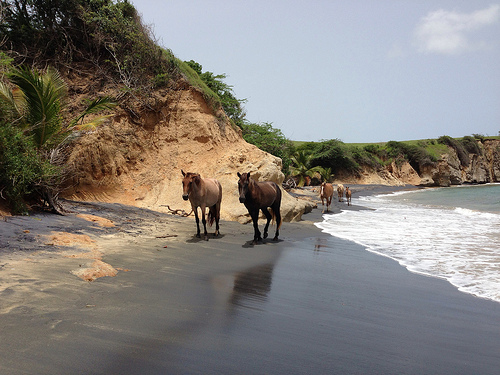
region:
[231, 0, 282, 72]
part of the sky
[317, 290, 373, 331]
edge of a shore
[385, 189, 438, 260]
part of a water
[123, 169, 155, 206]
part of a roack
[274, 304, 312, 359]
part of a shore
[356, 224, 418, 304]
edge of a shore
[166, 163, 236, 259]
Large brown animal walking on the beach.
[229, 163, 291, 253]
Dark brown animal walking on the beach.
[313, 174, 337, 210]
Brown animal walking on the beach.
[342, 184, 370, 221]
Brown animal walking along the beach.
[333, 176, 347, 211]
Brown animal walking along the beach.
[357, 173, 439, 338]
Waves washing up on shore.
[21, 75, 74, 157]
Large green leaves on plant.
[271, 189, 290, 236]
Horse has dark brown tail.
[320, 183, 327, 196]
Horse has white markings on face.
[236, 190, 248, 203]
Horse has dark face.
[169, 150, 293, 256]
two horses walking along beach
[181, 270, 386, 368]
ground covered in wet sand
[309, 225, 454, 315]
water crashing on wet beach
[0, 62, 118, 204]
large green fern leaves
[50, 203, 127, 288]
piles of brown sand on beach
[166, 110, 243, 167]
small cliff side covered in brown dirt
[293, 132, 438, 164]
top of hill covered in green grass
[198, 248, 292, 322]
reflection of horse in wet sand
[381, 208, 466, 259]
water covered in white sea foam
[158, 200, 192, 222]
brown tree limb laying on beach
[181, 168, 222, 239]
Brown Horse Walking Straight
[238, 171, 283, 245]
Brown Horse Walking Straight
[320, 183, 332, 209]
Brown Horse Walking Straight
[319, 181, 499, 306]
Water crashing on beach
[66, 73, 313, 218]
Pile of beach sand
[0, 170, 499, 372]
Wet beach with horses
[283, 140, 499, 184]
Sandy and Rocky Beach Ledge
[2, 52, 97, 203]
Beach side plants and trees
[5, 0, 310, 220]
Sandy and grassy hill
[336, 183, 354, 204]
2 Brown Horses Walking Straight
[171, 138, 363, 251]
A herd of horses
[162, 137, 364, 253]
The horses are on the beach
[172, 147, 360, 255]
The horses are standing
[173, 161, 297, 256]
Horses on the sand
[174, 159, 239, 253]
The horse is a red roan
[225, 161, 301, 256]
The horse is a dark bay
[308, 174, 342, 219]
Horse with a white blaze on its face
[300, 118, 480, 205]
Cliffs next to the water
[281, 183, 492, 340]
Waves washing on shore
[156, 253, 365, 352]
The sand is black